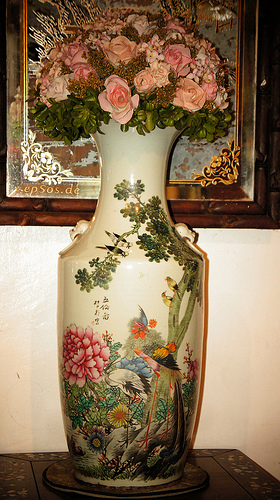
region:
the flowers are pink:
[204, 51, 225, 128]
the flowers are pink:
[68, 48, 184, 147]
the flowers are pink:
[56, 67, 146, 134]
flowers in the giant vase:
[33, 29, 217, 492]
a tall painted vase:
[39, 109, 227, 492]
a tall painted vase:
[48, 125, 214, 486]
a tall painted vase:
[54, 120, 232, 497]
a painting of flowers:
[50, 280, 200, 499]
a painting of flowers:
[44, 223, 198, 476]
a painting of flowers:
[55, 257, 201, 477]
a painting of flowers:
[44, 236, 194, 489]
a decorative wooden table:
[1, 447, 279, 498]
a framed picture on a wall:
[0, 0, 279, 226]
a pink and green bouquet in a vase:
[26, 10, 231, 146]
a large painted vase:
[50, 111, 209, 486]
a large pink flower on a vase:
[64, 325, 106, 383]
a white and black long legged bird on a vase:
[103, 345, 147, 453]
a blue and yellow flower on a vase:
[85, 431, 107, 454]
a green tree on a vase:
[74, 179, 202, 426]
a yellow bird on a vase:
[160, 290, 172, 306]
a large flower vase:
[54, 110, 219, 498]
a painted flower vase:
[48, 123, 238, 491]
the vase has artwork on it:
[58, 117, 223, 475]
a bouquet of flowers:
[14, 1, 244, 139]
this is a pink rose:
[155, 38, 200, 91]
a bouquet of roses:
[28, 10, 266, 138]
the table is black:
[4, 440, 278, 498]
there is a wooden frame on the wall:
[3, 0, 277, 234]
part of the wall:
[228, 368, 266, 412]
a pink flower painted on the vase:
[56, 316, 118, 392]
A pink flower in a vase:
[96, 74, 138, 122]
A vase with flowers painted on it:
[56, 117, 205, 494]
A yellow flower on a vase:
[107, 404, 131, 429]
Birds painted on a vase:
[161, 277, 180, 308]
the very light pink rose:
[97, 73, 140, 123]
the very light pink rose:
[45, 73, 75, 100]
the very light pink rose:
[101, 34, 140, 66]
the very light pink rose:
[171, 75, 205, 111]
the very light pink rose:
[163, 44, 191, 76]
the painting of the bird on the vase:
[104, 345, 148, 447]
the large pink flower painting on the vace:
[60, 323, 109, 384]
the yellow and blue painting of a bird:
[160, 289, 172, 307]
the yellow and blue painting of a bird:
[164, 276, 180, 300]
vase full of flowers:
[23, 3, 239, 497]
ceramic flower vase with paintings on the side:
[17, 8, 231, 490]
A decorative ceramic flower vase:
[15, 5, 237, 489]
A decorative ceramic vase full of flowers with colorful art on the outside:
[15, 13, 228, 489]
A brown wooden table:
[2, 446, 278, 499]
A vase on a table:
[0, 2, 277, 498]